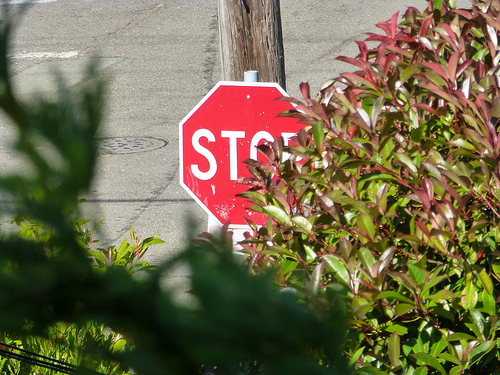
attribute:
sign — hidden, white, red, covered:
[177, 80, 326, 228]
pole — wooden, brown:
[217, 2, 286, 88]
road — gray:
[2, 0, 476, 310]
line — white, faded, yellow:
[9, 49, 77, 61]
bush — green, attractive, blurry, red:
[193, 0, 499, 374]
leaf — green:
[358, 171, 393, 193]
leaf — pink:
[337, 56, 376, 76]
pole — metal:
[244, 69, 259, 85]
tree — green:
[0, 2, 349, 375]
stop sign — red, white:
[178, 82, 307, 229]